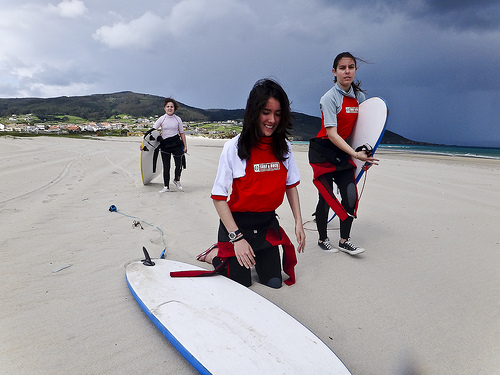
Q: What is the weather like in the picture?
A: It is cloudy.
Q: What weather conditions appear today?
A: It is cloudy.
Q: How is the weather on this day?
A: It is cloudy.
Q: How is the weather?
A: It is cloudy.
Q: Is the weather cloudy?
A: Yes, it is cloudy.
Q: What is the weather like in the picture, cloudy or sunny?
A: It is cloudy.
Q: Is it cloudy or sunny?
A: It is cloudy.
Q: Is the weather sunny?
A: No, it is cloudy.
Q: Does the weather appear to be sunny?
A: No, it is cloudy.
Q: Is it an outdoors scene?
A: Yes, it is outdoors.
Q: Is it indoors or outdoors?
A: It is outdoors.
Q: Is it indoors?
A: No, it is outdoors.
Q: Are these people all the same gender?
A: Yes, all the people are female.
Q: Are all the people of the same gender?
A: Yes, all the people are female.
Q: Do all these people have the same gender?
A: Yes, all the people are female.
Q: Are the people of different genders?
A: No, all the people are female.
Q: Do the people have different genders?
A: No, all the people are female.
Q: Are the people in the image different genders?
A: No, all the people are female.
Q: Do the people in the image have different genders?
A: No, all the people are female.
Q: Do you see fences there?
A: No, there are no fences.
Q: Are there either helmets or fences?
A: No, there are no fences or helmets.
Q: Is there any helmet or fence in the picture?
A: No, there are no fences or helmets.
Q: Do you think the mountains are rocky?
A: Yes, the mountains are rocky.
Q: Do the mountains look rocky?
A: Yes, the mountains are rocky.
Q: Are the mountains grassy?
A: No, the mountains are rocky.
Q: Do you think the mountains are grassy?
A: No, the mountains are rocky.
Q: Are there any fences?
A: No, there are no fences.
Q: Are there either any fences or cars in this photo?
A: No, there are no fences or cars.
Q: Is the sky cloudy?
A: Yes, the sky is cloudy.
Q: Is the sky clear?
A: No, the sky is cloudy.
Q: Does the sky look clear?
A: No, the sky is cloudy.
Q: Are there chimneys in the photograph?
A: No, there are no chimneys.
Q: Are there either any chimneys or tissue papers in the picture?
A: No, there are no chimneys or tissue papers.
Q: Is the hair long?
A: Yes, the hair is long.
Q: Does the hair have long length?
A: Yes, the hair is long.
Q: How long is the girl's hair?
A: The hair is long.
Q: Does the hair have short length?
A: No, the hair is long.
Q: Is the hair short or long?
A: The hair is long.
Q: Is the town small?
A: Yes, the town is small.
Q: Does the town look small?
A: Yes, the town is small.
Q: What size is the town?
A: The town is small.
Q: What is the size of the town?
A: The town is small.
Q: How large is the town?
A: The town is small.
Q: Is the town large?
A: No, the town is small.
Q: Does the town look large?
A: No, the town is small.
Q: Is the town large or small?
A: The town is small.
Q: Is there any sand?
A: Yes, there is sand.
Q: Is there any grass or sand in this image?
A: Yes, there is sand.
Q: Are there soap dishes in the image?
A: No, there are no soap dishes.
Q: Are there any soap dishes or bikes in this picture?
A: No, there are no soap dishes or bikes.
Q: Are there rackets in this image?
A: No, there are no rackets.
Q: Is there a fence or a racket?
A: No, there are no rackets or fences.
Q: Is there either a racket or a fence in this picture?
A: No, there are no rackets or fences.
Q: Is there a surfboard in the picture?
A: Yes, there is a surfboard.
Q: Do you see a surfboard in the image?
A: Yes, there is a surfboard.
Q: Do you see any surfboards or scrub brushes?
A: Yes, there is a surfboard.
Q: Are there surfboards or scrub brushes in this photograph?
A: Yes, there is a surfboard.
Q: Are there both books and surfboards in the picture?
A: No, there is a surfboard but no books.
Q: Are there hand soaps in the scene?
A: No, there are no hand soaps.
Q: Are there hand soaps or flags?
A: No, there are no hand soaps or flags.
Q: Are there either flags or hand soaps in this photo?
A: No, there are no hand soaps or flags.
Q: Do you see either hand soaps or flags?
A: No, there are no hand soaps or flags.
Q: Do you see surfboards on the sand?
A: Yes, there is a surfboard on the sand.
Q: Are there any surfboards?
A: Yes, there is a surfboard.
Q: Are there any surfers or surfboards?
A: Yes, there is a surfboard.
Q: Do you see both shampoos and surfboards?
A: No, there is a surfboard but no shampoos.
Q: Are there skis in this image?
A: No, there are no skis.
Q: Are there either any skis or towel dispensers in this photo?
A: No, there are no skis or towel dispensers.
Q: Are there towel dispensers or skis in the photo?
A: No, there are no skis or towel dispensers.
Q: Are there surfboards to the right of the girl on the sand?
A: Yes, there is a surfboard to the right of the girl.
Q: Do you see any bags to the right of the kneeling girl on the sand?
A: No, there is a surfboard to the right of the girl.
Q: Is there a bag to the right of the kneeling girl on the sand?
A: No, there is a surfboard to the right of the girl.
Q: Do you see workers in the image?
A: No, there are no workers.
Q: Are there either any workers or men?
A: No, there are no workers or men.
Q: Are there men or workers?
A: No, there are no workers or men.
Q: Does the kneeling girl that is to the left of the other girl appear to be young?
A: Yes, the girl is young.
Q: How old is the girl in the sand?
A: The girl is young.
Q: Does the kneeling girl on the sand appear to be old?
A: No, the girl is young.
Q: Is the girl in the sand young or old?
A: The girl is young.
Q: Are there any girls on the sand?
A: Yes, there is a girl on the sand.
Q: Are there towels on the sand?
A: No, there is a girl on the sand.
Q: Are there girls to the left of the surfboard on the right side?
A: Yes, there is a girl to the left of the surfboard.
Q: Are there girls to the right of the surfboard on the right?
A: No, the girl is to the left of the surfboard.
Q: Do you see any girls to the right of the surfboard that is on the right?
A: No, the girl is to the left of the surfboard.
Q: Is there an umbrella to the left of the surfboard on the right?
A: No, there is a girl to the left of the surfboard.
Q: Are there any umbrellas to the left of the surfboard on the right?
A: No, there is a girl to the left of the surfboard.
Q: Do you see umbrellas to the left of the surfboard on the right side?
A: No, there is a girl to the left of the surfboard.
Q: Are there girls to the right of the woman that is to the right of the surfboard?
A: Yes, there is a girl to the right of the woman.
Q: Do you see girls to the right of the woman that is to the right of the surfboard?
A: Yes, there is a girl to the right of the woman.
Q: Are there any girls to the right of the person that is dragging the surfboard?
A: Yes, there is a girl to the right of the woman.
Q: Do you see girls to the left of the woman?
A: No, the girl is to the right of the woman.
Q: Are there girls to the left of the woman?
A: No, the girl is to the right of the woman.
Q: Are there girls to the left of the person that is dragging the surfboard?
A: No, the girl is to the right of the woman.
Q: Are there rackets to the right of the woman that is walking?
A: No, there is a girl to the right of the woman.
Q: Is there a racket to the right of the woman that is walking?
A: No, there is a girl to the right of the woman.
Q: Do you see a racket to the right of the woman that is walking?
A: No, there is a girl to the right of the woman.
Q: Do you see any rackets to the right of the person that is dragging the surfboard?
A: No, there is a girl to the right of the woman.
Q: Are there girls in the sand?
A: Yes, there is a girl in the sand.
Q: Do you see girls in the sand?
A: Yes, there is a girl in the sand.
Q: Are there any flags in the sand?
A: No, there is a girl in the sand.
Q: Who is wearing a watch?
A: The girl is wearing a watch.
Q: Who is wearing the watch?
A: The girl is wearing a watch.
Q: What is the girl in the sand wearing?
A: The girl is wearing a watch.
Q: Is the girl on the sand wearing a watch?
A: Yes, the girl is wearing a watch.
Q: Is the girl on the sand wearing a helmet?
A: No, the girl is wearing a watch.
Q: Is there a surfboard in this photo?
A: Yes, there is a surfboard.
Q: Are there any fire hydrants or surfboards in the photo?
A: Yes, there is a surfboard.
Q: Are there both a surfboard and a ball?
A: No, there is a surfboard but no balls.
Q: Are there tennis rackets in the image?
A: No, there are no tennis rackets.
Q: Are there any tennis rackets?
A: No, there are no tennis rackets.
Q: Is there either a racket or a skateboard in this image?
A: No, there are no rackets or skateboards.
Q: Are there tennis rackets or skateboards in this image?
A: No, there are no tennis rackets or skateboards.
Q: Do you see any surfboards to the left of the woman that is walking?
A: Yes, there is a surfboard to the left of the woman.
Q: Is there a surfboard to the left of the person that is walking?
A: Yes, there is a surfboard to the left of the woman.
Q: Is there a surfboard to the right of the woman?
A: No, the surfboard is to the left of the woman.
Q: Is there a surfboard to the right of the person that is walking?
A: No, the surfboard is to the left of the woman.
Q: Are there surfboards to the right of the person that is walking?
A: No, the surfboard is to the left of the woman.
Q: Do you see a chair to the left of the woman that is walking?
A: No, there is a surfboard to the left of the woman.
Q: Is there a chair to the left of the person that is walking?
A: No, there is a surfboard to the left of the woman.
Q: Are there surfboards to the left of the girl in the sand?
A: Yes, there is a surfboard to the left of the girl.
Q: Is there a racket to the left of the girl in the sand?
A: No, there is a surfboard to the left of the girl.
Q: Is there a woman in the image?
A: Yes, there is a woman.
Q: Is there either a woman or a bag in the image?
A: Yes, there is a woman.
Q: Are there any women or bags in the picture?
A: Yes, there is a woman.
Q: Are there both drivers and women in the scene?
A: No, there is a woman but no drivers.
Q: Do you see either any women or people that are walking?
A: Yes, the woman is walking.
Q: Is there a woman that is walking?
A: Yes, there is a woman that is walking.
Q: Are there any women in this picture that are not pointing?
A: Yes, there is a woman that is walking.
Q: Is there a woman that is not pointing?
A: Yes, there is a woman that is walking.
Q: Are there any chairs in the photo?
A: No, there are no chairs.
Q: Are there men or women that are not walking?
A: No, there is a woman but she is walking.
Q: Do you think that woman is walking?
A: Yes, the woman is walking.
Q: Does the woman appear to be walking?
A: Yes, the woman is walking.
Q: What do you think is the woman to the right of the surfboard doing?
A: The woman is walking.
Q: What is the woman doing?
A: The woman is walking.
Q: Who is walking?
A: The woman is walking.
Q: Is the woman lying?
A: No, the woman is walking.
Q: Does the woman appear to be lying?
A: No, the woman is walking.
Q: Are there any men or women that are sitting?
A: No, there is a woman but she is walking.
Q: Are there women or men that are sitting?
A: No, there is a woman but she is walking.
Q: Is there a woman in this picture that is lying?
A: No, there is a woman but she is walking.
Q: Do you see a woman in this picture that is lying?
A: No, there is a woman but she is walking.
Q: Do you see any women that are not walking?
A: No, there is a woman but she is walking.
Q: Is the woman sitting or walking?
A: The woman is walking.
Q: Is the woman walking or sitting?
A: The woman is walking.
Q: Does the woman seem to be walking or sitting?
A: The woman is walking.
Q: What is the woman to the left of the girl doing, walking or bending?
A: The woman is walking.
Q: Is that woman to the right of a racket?
A: No, the woman is to the right of the surfboard.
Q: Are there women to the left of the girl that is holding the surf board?
A: Yes, there is a woman to the left of the girl.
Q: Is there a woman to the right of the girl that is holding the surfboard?
A: No, the woman is to the left of the girl.